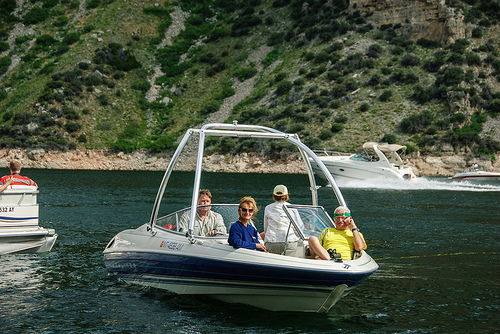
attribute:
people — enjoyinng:
[162, 149, 351, 277]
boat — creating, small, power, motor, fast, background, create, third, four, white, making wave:
[81, 136, 420, 315]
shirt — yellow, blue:
[311, 228, 360, 268]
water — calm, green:
[80, 174, 141, 231]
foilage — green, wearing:
[322, 205, 359, 227]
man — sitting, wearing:
[252, 192, 374, 313]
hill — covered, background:
[260, 40, 391, 124]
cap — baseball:
[268, 186, 298, 194]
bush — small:
[311, 72, 358, 131]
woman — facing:
[225, 188, 266, 257]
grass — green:
[141, 88, 186, 141]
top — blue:
[225, 224, 259, 248]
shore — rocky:
[464, 162, 483, 182]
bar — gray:
[213, 225, 254, 254]